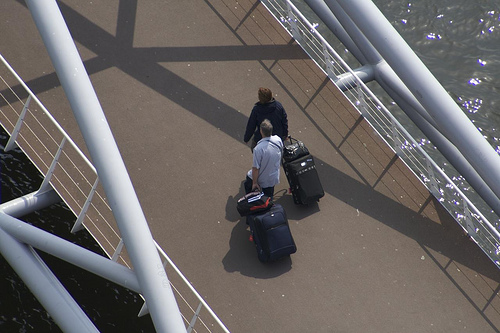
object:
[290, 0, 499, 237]
water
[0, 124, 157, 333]
water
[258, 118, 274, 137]
head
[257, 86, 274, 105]
head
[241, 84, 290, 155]
man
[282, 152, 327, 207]
suitcase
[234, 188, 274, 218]
tote bag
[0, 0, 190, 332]
rail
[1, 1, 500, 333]
bridge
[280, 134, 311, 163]
purse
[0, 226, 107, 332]
poles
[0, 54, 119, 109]
shadows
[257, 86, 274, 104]
red hair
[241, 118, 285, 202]
man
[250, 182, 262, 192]
hand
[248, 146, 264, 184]
arm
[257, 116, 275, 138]
hair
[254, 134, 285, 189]
back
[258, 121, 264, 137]
face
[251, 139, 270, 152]
shoulder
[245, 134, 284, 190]
shirt